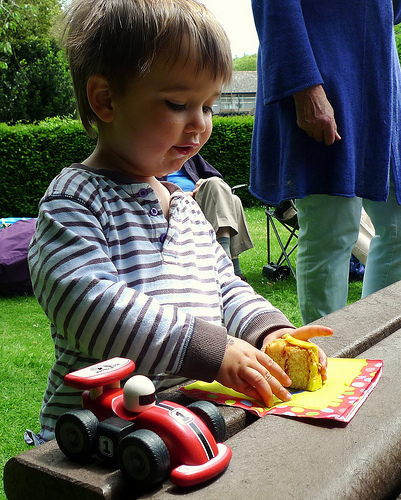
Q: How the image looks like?
A: Cute.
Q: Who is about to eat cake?
A: Little boy.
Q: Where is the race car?
A: Right of little boy.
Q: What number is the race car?
A: 1.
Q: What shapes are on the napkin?
A: Circles.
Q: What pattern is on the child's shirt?
A: Stripes.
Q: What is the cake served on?
A: Napkin.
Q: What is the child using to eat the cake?
A: Hands.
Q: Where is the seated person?
A: Behind the child.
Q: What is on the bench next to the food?
A: A red toy race car.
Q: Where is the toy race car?
A: On a bench next to the napkin.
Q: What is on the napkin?
A: A piece of cake.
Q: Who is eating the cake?
A: A young boy.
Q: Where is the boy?
A: Next to a bench.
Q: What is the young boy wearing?
A: A white and brown striped shirt.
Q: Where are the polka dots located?
A: On the yellow napkin.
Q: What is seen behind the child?
A: People sitting in camp chairs.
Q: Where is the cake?
A: On a yellow napkin.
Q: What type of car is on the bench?
A: A red toy car.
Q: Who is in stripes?
A: The child.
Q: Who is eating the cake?
A: The child.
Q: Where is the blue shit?
A: On the grown up.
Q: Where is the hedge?
A: In the distance.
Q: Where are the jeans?
A: On the grown up.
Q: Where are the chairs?
A: Behind the child.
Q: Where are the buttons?
A: On the child's shirt.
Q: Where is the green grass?
A: On the ground.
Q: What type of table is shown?
A: A picnic table.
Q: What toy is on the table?
A: A toy car.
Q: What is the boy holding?
A: A piece of cake.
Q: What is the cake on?
A: A napkin.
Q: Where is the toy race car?
A: On the bench to the left of the boy.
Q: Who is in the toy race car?
A: A toy driver.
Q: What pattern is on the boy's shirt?
A: Stripes.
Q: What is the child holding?
A: Cake.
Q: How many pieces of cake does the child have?
A: One.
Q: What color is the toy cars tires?
A: Black.